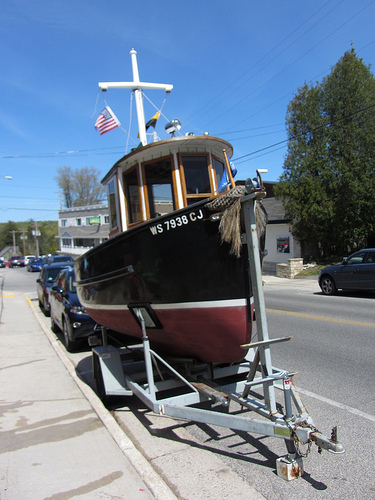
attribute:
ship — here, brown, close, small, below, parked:
[77, 127, 290, 381]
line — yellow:
[311, 306, 340, 332]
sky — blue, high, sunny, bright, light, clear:
[161, 3, 276, 94]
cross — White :
[98, 38, 197, 149]